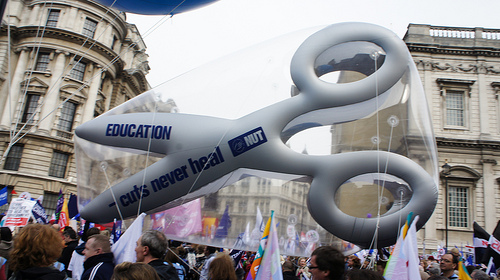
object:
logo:
[227, 126, 269, 158]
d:
[112, 124, 121, 137]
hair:
[2, 221, 62, 278]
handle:
[242, 22, 415, 128]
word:
[150, 164, 190, 193]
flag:
[456, 256, 472, 280]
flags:
[486, 219, 500, 276]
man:
[307, 243, 348, 280]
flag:
[110, 210, 148, 265]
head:
[3, 223, 73, 264]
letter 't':
[143, 124, 151, 138]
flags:
[211, 204, 232, 241]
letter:
[105, 124, 113, 137]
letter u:
[119, 124, 128, 137]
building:
[329, 22, 500, 265]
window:
[443, 87, 468, 128]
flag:
[246, 210, 290, 280]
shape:
[289, 21, 410, 106]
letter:
[162, 126, 172, 140]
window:
[21, 91, 42, 124]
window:
[32, 50, 51, 73]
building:
[0, 0, 154, 250]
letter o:
[153, 125, 164, 139]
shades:
[306, 256, 320, 280]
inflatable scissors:
[72, 22, 440, 248]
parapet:
[401, 23, 499, 51]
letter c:
[127, 124, 136, 138]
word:
[188, 145, 226, 175]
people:
[175, 242, 201, 280]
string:
[0, 0, 182, 165]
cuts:
[119, 184, 150, 207]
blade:
[77, 155, 209, 224]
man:
[80, 235, 113, 278]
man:
[134, 229, 180, 280]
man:
[437, 250, 460, 278]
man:
[54, 224, 81, 267]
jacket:
[77, 251, 116, 278]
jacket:
[142, 257, 180, 279]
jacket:
[6, 258, 66, 278]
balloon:
[87, 1, 225, 17]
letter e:
[105, 124, 114, 137]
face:
[307, 245, 345, 279]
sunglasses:
[307, 265, 325, 270]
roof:
[341, 50, 500, 76]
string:
[3, 3, 13, 144]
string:
[14, 0, 41, 130]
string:
[13, 7, 181, 150]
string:
[12, 8, 110, 141]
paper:
[152, 176, 313, 259]